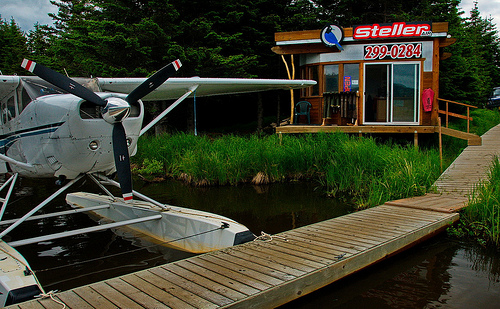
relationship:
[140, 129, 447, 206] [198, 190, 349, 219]
grass growing by water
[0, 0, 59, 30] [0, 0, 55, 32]
clouds in sky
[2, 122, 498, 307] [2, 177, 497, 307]
boardwalk wooden to lake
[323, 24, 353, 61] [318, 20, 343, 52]
bird in a logo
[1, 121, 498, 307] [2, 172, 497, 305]
dock along water